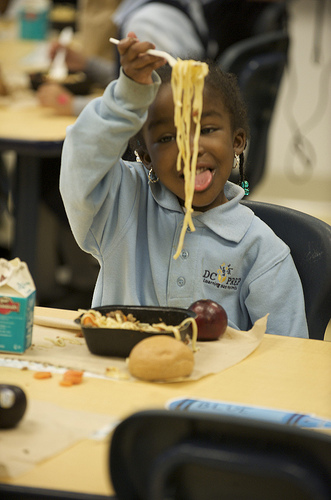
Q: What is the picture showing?
A: It is showing a cafeteria.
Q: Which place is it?
A: It is a cafeteria.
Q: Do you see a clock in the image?
A: No, there are no clocks.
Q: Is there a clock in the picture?
A: No, there are no clocks.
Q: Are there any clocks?
A: No, there are no clocks.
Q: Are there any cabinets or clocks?
A: No, there are no clocks or cabinets.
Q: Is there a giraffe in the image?
A: No, there are no giraffes.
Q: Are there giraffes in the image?
A: No, there are no giraffes.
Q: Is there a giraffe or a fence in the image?
A: No, there are no giraffes or fences.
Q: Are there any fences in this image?
A: No, there are no fences.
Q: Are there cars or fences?
A: No, there are no fences or cars.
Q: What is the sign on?
A: The sign is on the table.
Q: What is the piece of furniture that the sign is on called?
A: The piece of furniture is a table.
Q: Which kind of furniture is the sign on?
A: The sign is on the table.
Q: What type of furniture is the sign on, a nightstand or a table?
A: The sign is on a table.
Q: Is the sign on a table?
A: Yes, the sign is on a table.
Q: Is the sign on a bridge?
A: No, the sign is on a table.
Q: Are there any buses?
A: No, there are no buses.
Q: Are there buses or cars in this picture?
A: No, there are no buses or cars.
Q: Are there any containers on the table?
A: Yes, there is a container on the table.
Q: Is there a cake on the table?
A: No, there is a container on the table.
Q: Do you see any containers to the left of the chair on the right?
A: Yes, there is a container to the left of the chair.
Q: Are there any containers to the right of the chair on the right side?
A: No, the container is to the left of the chair.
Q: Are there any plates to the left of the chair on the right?
A: No, there is a container to the left of the chair.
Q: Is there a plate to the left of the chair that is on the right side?
A: No, there is a container to the left of the chair.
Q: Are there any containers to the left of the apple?
A: Yes, there is a container to the left of the apple.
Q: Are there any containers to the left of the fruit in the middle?
A: Yes, there is a container to the left of the apple.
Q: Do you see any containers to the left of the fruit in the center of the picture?
A: Yes, there is a container to the left of the apple.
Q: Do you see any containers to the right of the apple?
A: No, the container is to the left of the apple.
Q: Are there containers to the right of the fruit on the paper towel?
A: No, the container is to the left of the apple.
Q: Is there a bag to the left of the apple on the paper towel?
A: No, there is a container to the left of the apple.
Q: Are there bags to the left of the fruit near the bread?
A: No, there is a container to the left of the apple.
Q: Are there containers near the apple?
A: Yes, there is a container near the apple.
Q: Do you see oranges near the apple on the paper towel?
A: No, there is a container near the apple.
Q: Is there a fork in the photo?
A: Yes, there is a fork.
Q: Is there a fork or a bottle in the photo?
A: Yes, there is a fork.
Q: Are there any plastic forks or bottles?
A: Yes, there is a plastic fork.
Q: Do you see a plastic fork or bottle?
A: Yes, there is a plastic fork.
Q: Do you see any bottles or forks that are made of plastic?
A: Yes, the fork is made of plastic.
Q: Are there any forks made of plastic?
A: Yes, there is a fork that is made of plastic.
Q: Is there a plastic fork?
A: Yes, there is a fork that is made of plastic.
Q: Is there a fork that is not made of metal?
A: Yes, there is a fork that is made of plastic.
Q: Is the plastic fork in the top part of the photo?
A: Yes, the fork is in the top of the image.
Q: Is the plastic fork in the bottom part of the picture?
A: No, the fork is in the top of the image.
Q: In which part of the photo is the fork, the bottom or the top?
A: The fork is in the top of the image.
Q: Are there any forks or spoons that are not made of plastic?
A: No, there is a fork but it is made of plastic.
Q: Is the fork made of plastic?
A: Yes, the fork is made of plastic.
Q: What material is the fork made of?
A: The fork is made of plastic.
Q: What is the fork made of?
A: The fork is made of plastic.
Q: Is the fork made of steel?
A: No, the fork is made of plastic.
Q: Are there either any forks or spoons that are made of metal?
A: No, there is a fork but it is made of plastic.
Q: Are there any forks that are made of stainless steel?
A: No, there is a fork but it is made of plastic.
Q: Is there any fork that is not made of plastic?
A: No, there is a fork but it is made of plastic.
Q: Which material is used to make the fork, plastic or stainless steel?
A: The fork is made of plastic.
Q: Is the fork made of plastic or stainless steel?
A: The fork is made of plastic.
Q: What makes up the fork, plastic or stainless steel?
A: The fork is made of plastic.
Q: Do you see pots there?
A: No, there are no pots.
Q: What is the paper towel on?
A: The paper towel is on the table.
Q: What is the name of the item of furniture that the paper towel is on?
A: The piece of furniture is a table.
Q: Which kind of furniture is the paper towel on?
A: The paper towel is on the table.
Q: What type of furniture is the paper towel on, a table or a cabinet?
A: The paper towel is on a table.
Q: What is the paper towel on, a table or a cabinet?
A: The paper towel is on a table.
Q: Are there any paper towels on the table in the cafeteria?
A: Yes, there is a paper towel on the table.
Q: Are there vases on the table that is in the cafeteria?
A: No, there is a paper towel on the table.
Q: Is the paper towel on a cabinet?
A: No, the paper towel is on a table.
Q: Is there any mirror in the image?
A: No, there are no mirrors.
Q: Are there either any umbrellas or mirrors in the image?
A: No, there are no mirrors or umbrellas.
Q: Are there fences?
A: No, there are no fences.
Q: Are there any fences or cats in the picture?
A: No, there are no fences or cats.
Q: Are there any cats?
A: No, there are no cats.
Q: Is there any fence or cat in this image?
A: No, there are no cats or fences.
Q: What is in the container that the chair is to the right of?
A: The noodles are in the container.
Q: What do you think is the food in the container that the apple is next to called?
A: The food is noodles.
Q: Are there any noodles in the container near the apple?
A: Yes, there are noodles in the container.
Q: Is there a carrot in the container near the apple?
A: No, there are noodles in the container.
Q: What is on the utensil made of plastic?
A: The noodles are on the fork.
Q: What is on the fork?
A: The noodles are on the fork.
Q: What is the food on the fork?
A: The food is noodles.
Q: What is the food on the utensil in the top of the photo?
A: The food is noodles.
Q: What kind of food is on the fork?
A: The food is noodles.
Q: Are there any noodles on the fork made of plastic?
A: Yes, there are noodles on the fork.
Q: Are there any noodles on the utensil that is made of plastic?
A: Yes, there are noodles on the fork.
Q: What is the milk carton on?
A: The milk carton is on the table.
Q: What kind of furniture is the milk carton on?
A: The milk carton is on the table.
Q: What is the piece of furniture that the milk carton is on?
A: The piece of furniture is a table.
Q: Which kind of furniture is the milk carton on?
A: The milk carton is on the table.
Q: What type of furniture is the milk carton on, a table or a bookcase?
A: The milk carton is on a table.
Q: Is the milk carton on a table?
A: Yes, the milk carton is on a table.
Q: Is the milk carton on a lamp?
A: No, the milk carton is on a table.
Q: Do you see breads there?
A: Yes, there is a bread.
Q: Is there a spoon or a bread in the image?
A: Yes, there is a bread.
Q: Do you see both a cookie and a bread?
A: No, there is a bread but no cookies.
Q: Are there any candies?
A: No, there are no candies.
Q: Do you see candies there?
A: No, there are no candies.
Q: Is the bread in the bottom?
A: Yes, the bread is in the bottom of the image.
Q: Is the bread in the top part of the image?
A: No, the bread is in the bottom of the image.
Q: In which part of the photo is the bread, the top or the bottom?
A: The bread is in the bottom of the image.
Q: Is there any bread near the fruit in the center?
A: Yes, there is a bread near the apple.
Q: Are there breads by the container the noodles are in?
A: Yes, there is a bread by the container.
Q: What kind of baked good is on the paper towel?
A: The food is a bread.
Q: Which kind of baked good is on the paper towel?
A: The food is a bread.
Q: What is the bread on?
A: The bread is on the paper towel.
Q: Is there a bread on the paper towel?
A: Yes, there is a bread on the paper towel.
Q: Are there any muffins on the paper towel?
A: No, there is a bread on the paper towel.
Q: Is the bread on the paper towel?
A: Yes, the bread is on the paper towel.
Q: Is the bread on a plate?
A: No, the bread is on the paper towel.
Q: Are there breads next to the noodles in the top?
A: Yes, there is a bread next to the noodles.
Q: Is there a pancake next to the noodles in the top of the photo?
A: No, there is a bread next to the noodles.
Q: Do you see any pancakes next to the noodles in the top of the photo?
A: No, there is a bread next to the noodles.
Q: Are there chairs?
A: Yes, there is a chair.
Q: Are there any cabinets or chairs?
A: Yes, there is a chair.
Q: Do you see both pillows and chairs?
A: No, there is a chair but no pillows.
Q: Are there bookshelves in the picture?
A: No, there are no bookshelves.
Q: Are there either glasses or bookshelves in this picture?
A: No, there are no bookshelves or glasses.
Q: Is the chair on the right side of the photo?
A: Yes, the chair is on the right of the image.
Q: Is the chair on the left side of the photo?
A: No, the chair is on the right of the image.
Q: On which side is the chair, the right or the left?
A: The chair is on the right of the image.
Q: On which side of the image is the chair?
A: The chair is on the right of the image.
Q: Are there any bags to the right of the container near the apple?
A: No, there is a chair to the right of the container.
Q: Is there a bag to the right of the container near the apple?
A: No, there is a chair to the right of the container.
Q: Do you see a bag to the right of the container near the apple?
A: No, there is a chair to the right of the container.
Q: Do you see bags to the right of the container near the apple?
A: No, there is a chair to the right of the container.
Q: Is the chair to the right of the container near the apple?
A: Yes, the chair is to the right of the container.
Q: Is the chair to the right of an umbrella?
A: No, the chair is to the right of the container.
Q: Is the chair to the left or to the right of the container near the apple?
A: The chair is to the right of the container.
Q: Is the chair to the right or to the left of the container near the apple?
A: The chair is to the right of the container.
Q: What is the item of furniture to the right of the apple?
A: The piece of furniture is a chair.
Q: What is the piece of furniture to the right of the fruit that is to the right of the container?
A: The piece of furniture is a chair.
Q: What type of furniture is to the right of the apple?
A: The piece of furniture is a chair.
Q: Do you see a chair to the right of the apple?
A: Yes, there is a chair to the right of the apple.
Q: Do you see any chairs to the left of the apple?
A: No, the chair is to the right of the apple.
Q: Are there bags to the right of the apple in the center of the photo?
A: No, there is a chair to the right of the apple.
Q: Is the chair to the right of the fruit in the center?
A: Yes, the chair is to the right of the apple.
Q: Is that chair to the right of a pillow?
A: No, the chair is to the right of the apple.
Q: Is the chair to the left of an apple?
A: No, the chair is to the right of an apple.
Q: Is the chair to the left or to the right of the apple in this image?
A: The chair is to the right of the apple.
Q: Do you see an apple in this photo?
A: Yes, there is an apple.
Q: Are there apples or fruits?
A: Yes, there is an apple.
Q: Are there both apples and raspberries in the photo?
A: No, there is an apple but no raspberries.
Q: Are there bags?
A: No, there are no bags.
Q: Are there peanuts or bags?
A: No, there are no bags or peanuts.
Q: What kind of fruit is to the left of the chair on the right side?
A: The fruit is an apple.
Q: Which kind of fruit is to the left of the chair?
A: The fruit is an apple.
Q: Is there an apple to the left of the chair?
A: Yes, there is an apple to the left of the chair.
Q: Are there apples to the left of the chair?
A: Yes, there is an apple to the left of the chair.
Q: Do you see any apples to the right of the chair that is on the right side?
A: No, the apple is to the left of the chair.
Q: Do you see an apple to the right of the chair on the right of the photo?
A: No, the apple is to the left of the chair.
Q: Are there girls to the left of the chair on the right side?
A: No, there is an apple to the left of the chair.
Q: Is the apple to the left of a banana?
A: No, the apple is to the left of the chair.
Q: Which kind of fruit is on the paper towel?
A: The fruit is an apple.